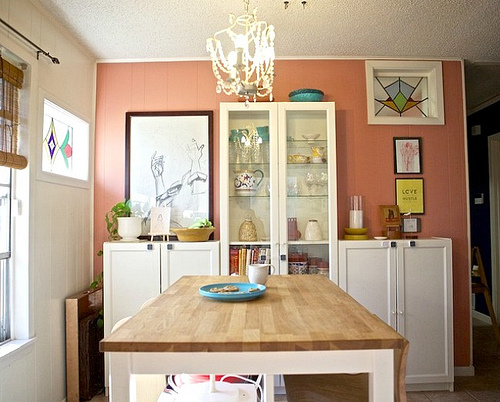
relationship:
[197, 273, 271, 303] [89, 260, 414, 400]
plate on table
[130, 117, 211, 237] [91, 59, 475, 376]
picture hanging on wall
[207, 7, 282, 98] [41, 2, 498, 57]
chandelier hanging ceiling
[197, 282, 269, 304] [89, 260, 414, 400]
plate on table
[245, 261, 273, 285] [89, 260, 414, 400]
cup on table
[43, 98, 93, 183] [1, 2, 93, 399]
window on wall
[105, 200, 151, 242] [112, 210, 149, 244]
plant in vase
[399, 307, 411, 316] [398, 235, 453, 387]
knob on cabinet door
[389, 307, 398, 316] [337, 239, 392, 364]
knob on cabinet door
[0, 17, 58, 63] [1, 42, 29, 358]
rod above window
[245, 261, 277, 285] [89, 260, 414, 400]
cup on table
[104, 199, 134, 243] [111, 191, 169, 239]
plant in pot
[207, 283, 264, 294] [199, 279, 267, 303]
cookies on plate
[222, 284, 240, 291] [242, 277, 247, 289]
cookies on plate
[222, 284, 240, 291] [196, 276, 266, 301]
cookies on plate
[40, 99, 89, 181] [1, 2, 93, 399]
window in wall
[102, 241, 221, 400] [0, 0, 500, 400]
cabinet in dining room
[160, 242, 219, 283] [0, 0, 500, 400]
cabinet in dining room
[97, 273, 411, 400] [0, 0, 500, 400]
table in dining room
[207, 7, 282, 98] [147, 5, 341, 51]
chandelier hangs from ceiling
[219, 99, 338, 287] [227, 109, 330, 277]
cabinet with windows